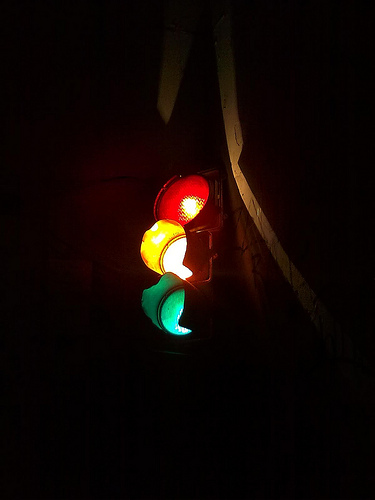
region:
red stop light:
[143, 170, 220, 224]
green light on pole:
[132, 276, 207, 345]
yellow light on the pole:
[136, 224, 211, 278]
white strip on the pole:
[213, 108, 255, 163]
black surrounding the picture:
[219, 401, 302, 444]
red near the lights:
[71, 168, 132, 200]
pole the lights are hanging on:
[232, 225, 263, 278]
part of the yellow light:
[197, 234, 216, 282]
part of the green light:
[196, 296, 209, 335]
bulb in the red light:
[175, 195, 207, 221]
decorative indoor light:
[135, 167, 226, 352]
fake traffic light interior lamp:
[133, 167, 228, 351]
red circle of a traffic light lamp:
[158, 172, 212, 223]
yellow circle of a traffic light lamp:
[137, 219, 202, 280]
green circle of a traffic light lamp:
[143, 274, 199, 335]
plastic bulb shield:
[178, 196, 199, 218]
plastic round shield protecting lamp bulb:
[156, 232, 195, 278]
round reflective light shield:
[138, 271, 208, 340]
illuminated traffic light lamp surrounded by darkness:
[2, 1, 371, 498]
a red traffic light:
[147, 166, 220, 228]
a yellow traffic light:
[136, 218, 199, 280]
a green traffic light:
[151, 271, 198, 337]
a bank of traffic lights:
[132, 164, 234, 364]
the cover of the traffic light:
[133, 269, 210, 344]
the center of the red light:
[175, 190, 203, 224]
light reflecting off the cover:
[150, 229, 166, 245]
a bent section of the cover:
[141, 271, 165, 292]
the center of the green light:
[172, 310, 191, 333]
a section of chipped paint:
[232, 119, 246, 146]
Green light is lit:
[156, 287, 191, 333]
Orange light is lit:
[151, 233, 193, 276]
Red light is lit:
[159, 172, 207, 226]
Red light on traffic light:
[154, 171, 207, 228]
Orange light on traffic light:
[158, 232, 195, 277]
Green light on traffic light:
[155, 285, 194, 335]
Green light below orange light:
[153, 286, 191, 333]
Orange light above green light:
[155, 233, 195, 276]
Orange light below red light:
[161, 233, 197, 276]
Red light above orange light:
[158, 175, 206, 223]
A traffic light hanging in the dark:
[138, 167, 240, 349]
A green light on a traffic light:
[138, 279, 207, 340]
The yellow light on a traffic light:
[134, 223, 209, 276]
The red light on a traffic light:
[150, 168, 216, 222]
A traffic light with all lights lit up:
[143, 171, 222, 348]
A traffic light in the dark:
[17, 52, 363, 468]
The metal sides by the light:
[179, 276, 218, 330]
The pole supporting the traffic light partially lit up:
[223, 168, 295, 393]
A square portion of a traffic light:
[152, 166, 232, 235]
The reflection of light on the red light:
[180, 191, 201, 217]